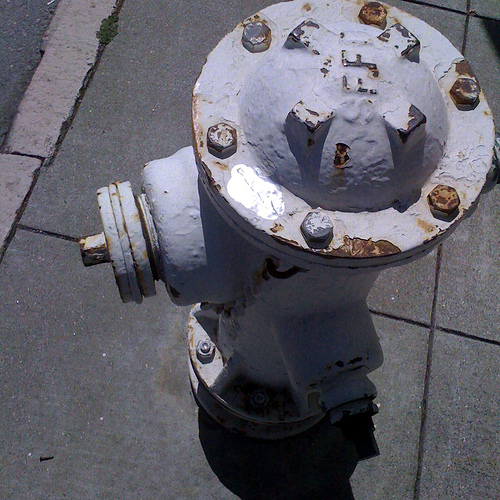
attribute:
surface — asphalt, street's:
[13, 24, 104, 112]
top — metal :
[238, 31, 485, 233]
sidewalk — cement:
[3, 4, 498, 498]